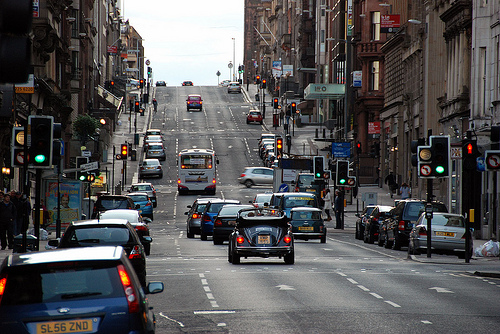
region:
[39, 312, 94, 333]
A yellow license plate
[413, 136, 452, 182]
Stoplight on a pole.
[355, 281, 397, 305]
White lines on the ground.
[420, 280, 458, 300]
Arrow on the road.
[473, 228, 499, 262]
Trash bag on the curb.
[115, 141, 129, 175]
Orange lights on a pole.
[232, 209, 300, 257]
The car is a convertible.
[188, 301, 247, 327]
Manhole cover on the road.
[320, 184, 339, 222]
Person stepping on the road.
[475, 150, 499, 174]
Arrow with a line through it.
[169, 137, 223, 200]
White bus on road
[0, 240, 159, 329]
Blue car idle near sidewalk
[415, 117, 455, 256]
Stop light switched to green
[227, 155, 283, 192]
White car crossing intersection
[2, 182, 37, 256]
People standing on sidewalk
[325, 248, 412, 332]
White lines on road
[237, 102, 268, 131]
Red car parked uphill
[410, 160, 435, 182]
No left turn sign near light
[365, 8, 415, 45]
Red and black sign on building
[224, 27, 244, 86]
Light post at top of hill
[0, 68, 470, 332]
Several cars are on the street.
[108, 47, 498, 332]
The street is in San Francisco.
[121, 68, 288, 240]
The street is on a hill.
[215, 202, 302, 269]
The car is a Volkswagen Beetle.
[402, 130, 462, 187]
The traffic light is green.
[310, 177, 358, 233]
People stand on the street.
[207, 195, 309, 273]
The car is a convertible.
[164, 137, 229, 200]
The bus is white.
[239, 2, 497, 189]
Several buildings line the street.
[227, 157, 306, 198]
The car is crossing the street.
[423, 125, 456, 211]
a traffic light on the side of street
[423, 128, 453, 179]
traffic light is color green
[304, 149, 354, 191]
two traffic lights on a corner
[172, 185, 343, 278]
cars stopped on the corner of street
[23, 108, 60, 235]
traffic light on left side of street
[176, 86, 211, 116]
a red car travels on a hill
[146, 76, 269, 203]
road is on a hill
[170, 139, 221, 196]
a bus traveling forward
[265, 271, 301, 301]
arrow point forward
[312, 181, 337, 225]
person stands on right side of the street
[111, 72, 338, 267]
A lot of cars are on the street.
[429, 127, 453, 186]
A traffic light.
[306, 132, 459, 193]
A row of traffic lights.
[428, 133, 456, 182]
The traffic light is green.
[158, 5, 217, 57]
The sky is white.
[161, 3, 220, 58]
The sky is cloudy.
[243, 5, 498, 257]
Buildings line the sides of the street.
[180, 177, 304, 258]
Cars have their lights on.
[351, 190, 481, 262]
Cars are parked on the side of the street.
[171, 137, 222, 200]
A bus is driving down the street.